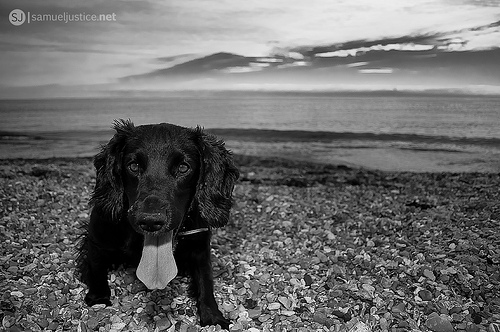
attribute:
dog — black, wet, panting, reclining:
[80, 118, 238, 327]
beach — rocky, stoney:
[3, 136, 499, 332]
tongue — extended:
[133, 229, 178, 288]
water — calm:
[1, 93, 500, 142]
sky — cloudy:
[3, 0, 475, 90]